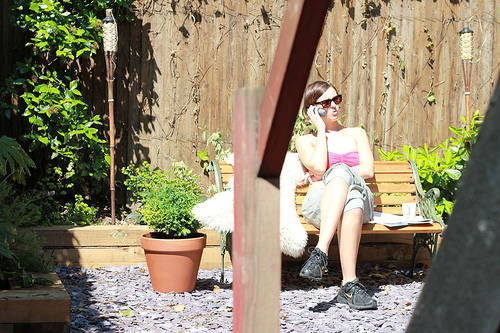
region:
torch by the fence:
[101, 8, 118, 223]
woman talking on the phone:
[296, 79, 379, 310]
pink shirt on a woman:
[326, 150, 358, 167]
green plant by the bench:
[134, 171, 205, 236]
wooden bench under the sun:
[211, 158, 446, 280]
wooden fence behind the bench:
[115, 0, 499, 208]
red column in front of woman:
[233, 0, 332, 332]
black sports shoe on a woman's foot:
[334, 279, 376, 309]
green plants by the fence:
[1, 0, 108, 222]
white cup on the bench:
[401, 202, 415, 219]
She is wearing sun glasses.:
[315, 88, 345, 109]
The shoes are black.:
[296, 246, 378, 316]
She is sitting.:
[300, 91, 378, 305]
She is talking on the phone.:
[296, 82, 386, 317]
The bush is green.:
[114, 153, 203, 228]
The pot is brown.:
[133, 227, 215, 298]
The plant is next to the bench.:
[120, 153, 242, 300]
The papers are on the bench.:
[368, 207, 425, 232]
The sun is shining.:
[19, 13, 427, 332]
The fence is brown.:
[121, 3, 498, 170]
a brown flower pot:
[86, 140, 207, 329]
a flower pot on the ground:
[109, 153, 226, 320]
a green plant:
[109, 151, 214, 312]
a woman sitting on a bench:
[185, 85, 460, 287]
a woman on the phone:
[276, 71, 417, 267]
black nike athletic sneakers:
[273, 248, 390, 322]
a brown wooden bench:
[178, 120, 498, 310]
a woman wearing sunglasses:
[267, 75, 372, 165]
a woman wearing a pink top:
[271, 83, 413, 248]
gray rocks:
[74, 260, 339, 331]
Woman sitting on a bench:
[277, 78, 394, 317]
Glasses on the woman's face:
[316, 92, 351, 112]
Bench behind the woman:
[201, 153, 451, 287]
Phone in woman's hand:
[300, 98, 336, 129]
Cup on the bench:
[391, 188, 419, 226]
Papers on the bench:
[362, 203, 435, 238]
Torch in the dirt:
[89, 5, 135, 229]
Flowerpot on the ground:
[132, 158, 214, 293]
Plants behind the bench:
[372, 103, 494, 234]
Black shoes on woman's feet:
[294, 243, 379, 315]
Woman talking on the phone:
[291, 78, 379, 181]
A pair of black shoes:
[297, 243, 380, 312]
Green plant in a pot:
[122, 155, 214, 296]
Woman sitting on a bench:
[205, 75, 449, 289]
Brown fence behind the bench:
[59, 25, 498, 196]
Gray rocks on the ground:
[55, 263, 427, 330]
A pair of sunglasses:
[307, 91, 345, 111]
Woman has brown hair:
[296, 77, 346, 124]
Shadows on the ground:
[194, 262, 429, 315]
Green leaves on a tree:
[1, 25, 113, 221]